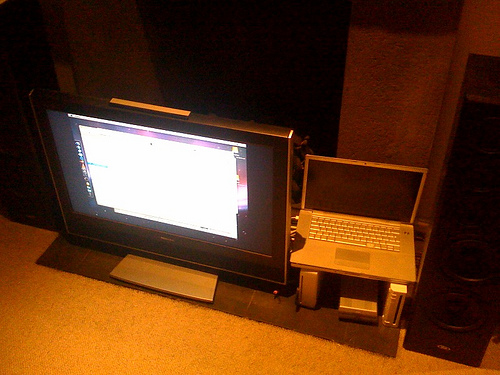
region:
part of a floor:
[138, 318, 157, 340]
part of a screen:
[190, 210, 215, 240]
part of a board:
[343, 252, 387, 310]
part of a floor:
[200, 314, 223, 350]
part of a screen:
[175, 195, 220, 259]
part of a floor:
[192, 314, 209, 331]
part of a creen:
[179, 249, 206, 271]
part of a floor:
[142, 306, 167, 330]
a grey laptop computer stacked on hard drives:
[290, 150, 421, 285]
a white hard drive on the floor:
[378, 282, 408, 335]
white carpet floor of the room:
[61, 305, 203, 347]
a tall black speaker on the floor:
[419, 91, 498, 373]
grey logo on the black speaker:
[434, 337, 455, 358]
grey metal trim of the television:
[192, 117, 279, 142]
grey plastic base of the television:
[103, 247, 233, 312]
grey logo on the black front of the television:
[157, 232, 174, 248]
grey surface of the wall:
[362, 20, 437, 142]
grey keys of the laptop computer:
[299, 209, 406, 254]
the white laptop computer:
[292, 141, 420, 286]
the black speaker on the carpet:
[405, 57, 497, 372]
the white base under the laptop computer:
[295, 270, 404, 335]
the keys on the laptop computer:
[304, 216, 401, 256]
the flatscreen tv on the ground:
[35, 91, 297, 313]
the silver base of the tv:
[92, 258, 224, 310]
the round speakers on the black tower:
[425, 225, 499, 338]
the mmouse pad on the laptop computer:
[330, 243, 374, 273]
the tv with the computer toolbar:
[72, 116, 97, 209]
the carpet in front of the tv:
[3, 308, 291, 373]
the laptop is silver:
[281, 140, 440, 306]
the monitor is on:
[29, 80, 291, 317]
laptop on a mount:
[286, 150, 428, 280]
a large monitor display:
[15, 80, 290, 290]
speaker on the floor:
[392, 70, 497, 360]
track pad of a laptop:
[331, 245, 367, 275]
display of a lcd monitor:
[45, 110, 277, 257]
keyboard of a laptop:
[305, 201, 410, 253]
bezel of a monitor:
[102, 246, 227, 298]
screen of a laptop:
[306, 160, 416, 225]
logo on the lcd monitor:
[153, 233, 179, 245]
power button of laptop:
[400, 229, 412, 236]